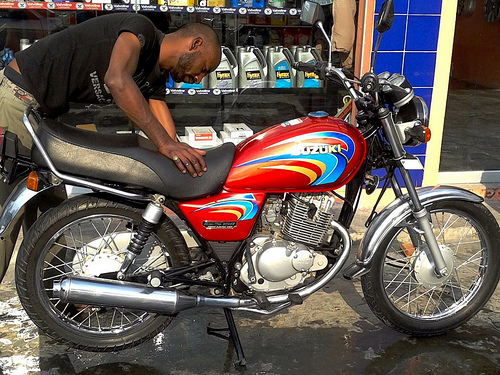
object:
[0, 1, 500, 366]
motorbike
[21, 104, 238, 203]
seat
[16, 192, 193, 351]
wheel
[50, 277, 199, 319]
pipe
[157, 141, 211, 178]
hand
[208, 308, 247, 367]
stand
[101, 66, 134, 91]
elbow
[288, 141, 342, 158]
emblem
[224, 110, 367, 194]
tank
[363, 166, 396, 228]
brakes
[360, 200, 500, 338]
wheel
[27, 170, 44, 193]
signal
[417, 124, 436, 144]
signal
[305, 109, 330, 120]
cap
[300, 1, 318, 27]
mirror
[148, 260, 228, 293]
kickstarter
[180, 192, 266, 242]
guard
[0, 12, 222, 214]
man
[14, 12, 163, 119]
shirt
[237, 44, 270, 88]
bottle